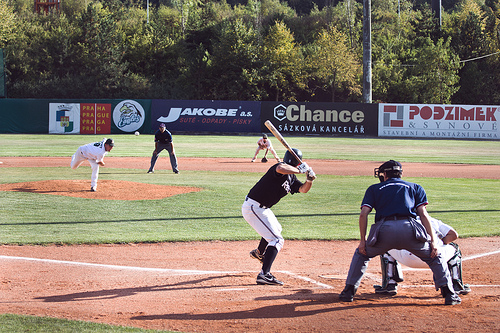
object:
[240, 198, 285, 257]
pants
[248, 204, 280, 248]
stripe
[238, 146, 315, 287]
batter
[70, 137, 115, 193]
pitcher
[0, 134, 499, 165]
green field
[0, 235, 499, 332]
brown field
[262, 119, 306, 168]
bat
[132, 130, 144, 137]
ball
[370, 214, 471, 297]
catcher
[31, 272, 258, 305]
shadows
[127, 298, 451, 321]
shadow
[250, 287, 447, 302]
shadow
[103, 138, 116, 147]
cap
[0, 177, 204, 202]
mound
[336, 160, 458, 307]
ump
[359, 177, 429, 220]
shirt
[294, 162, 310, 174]
hand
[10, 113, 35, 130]
air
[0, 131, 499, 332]
field